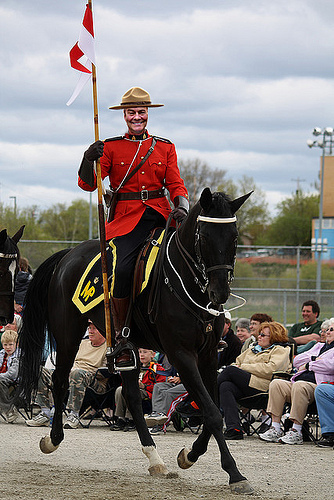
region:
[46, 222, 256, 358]
black horse is trotting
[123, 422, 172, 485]
horse has white leg at bottom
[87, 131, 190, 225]
man has on red jacket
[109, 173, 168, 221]
red jacket with black belt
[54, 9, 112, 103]
flag is red and white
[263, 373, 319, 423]
lady with tan slacks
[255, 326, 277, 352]
lady wearing dark sunglasses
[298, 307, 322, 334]
smiling man wearing green shirt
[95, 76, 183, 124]
smiling man wearing tan hat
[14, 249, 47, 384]
horse has long black tail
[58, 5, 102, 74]
red and white flag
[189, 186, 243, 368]
black horse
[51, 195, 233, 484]
black horse being ridden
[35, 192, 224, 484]
black horse being ridden by officer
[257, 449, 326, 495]
gray dirt and rocks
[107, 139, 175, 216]
officer wearing red jacket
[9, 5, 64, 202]
white and gray clouds against blue sky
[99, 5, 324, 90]
white and gray clouds against blue sky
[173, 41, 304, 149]
white and gray clouds against blue sky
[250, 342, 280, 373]
woman wearing tan jacket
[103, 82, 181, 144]
a man wearing a hat.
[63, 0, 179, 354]
a man holding up a flag.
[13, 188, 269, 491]
a dark haired horse.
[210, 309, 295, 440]
a woman sitting on a chair.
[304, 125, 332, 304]
lights outside of a building.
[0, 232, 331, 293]
a chain link fence.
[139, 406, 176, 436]
a pair of white shoes.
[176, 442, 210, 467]
a horse left hoof.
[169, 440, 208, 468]
a horse shoed hoof.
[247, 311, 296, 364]
a woman with red hair.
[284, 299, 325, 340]
MAN WEARING A GREEN SHIRT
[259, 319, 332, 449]
WOMAN WEARING WHITE SNEAKERS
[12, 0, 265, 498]
MAN RIDING ON A HORSE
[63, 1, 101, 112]
RED AND WHITE FLAG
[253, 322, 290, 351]
WOMAN WEARING SUNGLASSES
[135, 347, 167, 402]
BOY WEARING A RED COAT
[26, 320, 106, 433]
MAN WEARING CAMOUFLAGE PANTS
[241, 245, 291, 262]
CARS IN THE BACKGROUND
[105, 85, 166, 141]
MAN WEARING A HAT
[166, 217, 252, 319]
HORSE WITH A WHITE BRIDLE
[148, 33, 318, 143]
The sky is overcast.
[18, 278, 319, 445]
The people are sitting.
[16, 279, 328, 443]
The people are watching.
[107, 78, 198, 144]
He is wearing a hat.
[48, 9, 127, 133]
He is carrying a flag.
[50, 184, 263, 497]
The horse is black.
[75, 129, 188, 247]
He is wearing a red shirt.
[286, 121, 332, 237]
The lights are off.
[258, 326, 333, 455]
She is wearing a pink jacket.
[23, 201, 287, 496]
The horse is trotting.